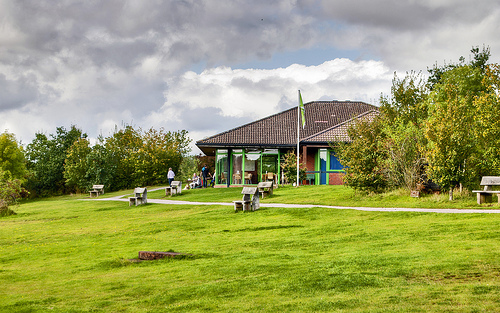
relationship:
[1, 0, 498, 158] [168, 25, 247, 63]
cloud has part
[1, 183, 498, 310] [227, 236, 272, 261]
field has part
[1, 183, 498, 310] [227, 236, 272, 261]
grass has part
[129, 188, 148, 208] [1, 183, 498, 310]
seat on grass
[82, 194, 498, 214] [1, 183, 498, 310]
walk way between grass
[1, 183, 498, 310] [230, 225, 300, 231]
grass has dark patch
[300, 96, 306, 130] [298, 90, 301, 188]
flag hanging on flag pole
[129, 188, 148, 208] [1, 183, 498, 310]
seat in grass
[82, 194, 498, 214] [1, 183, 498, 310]
walk way cutting through grass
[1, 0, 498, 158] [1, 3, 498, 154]
cloud in sky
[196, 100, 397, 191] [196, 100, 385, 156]
building has roof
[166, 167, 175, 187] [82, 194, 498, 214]
person walking on walk way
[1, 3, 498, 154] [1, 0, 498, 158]
sky between cloud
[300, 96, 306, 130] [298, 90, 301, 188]
flag on flag pole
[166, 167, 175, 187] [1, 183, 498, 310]
person standing in grass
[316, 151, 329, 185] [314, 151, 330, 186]
blue entrance has green border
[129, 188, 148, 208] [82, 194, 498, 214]
seat along walk way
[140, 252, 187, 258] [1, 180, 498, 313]
slab of cement in yard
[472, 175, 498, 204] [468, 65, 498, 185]
bench under tree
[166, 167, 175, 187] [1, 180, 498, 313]
person walking in yard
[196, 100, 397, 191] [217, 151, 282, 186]
building has patio porch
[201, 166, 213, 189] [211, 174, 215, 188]
person cooking on grill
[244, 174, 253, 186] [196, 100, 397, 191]
patio furniture inside of building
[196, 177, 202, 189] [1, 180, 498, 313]
person in yard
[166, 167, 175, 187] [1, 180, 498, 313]
person in yard